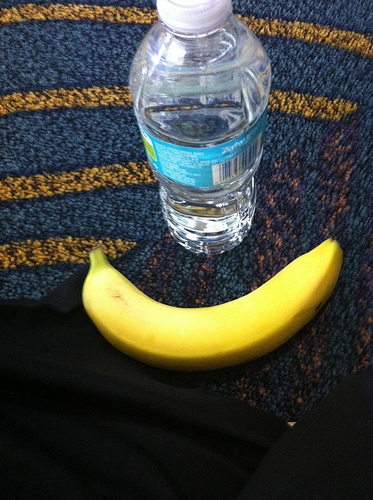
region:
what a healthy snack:
[17, 0, 361, 335]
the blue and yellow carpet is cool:
[4, 7, 120, 208]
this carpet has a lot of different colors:
[267, 158, 364, 231]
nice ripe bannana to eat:
[70, 241, 350, 373]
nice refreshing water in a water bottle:
[119, 19, 281, 262]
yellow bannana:
[80, 241, 357, 373]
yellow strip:
[1, 81, 127, 119]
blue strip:
[2, 111, 136, 170]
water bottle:
[116, 0, 292, 269]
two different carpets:
[288, 74, 372, 212]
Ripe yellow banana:
[65, 231, 357, 381]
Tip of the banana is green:
[83, 245, 117, 275]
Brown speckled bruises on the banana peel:
[102, 277, 147, 314]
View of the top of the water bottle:
[117, 1, 274, 262]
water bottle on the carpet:
[118, 1, 276, 263]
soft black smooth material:
[0, 299, 372, 499]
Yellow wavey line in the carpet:
[2, 0, 372, 276]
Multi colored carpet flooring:
[0, 0, 370, 427]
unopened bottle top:
[150, 0, 239, 47]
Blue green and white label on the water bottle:
[126, 116, 276, 196]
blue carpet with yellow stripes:
[4, 4, 371, 396]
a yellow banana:
[85, 241, 341, 368]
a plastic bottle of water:
[128, 0, 270, 255]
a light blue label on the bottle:
[136, 111, 266, 190]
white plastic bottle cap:
[156, 1, 234, 31]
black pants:
[0, 301, 371, 497]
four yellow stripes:
[0, 5, 370, 265]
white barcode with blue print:
[210, 133, 262, 185]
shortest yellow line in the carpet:
[3, 233, 139, 272]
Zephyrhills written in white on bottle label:
[220, 122, 258, 155]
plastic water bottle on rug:
[138, 0, 273, 256]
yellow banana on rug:
[68, 271, 331, 387]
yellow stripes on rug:
[20, 202, 115, 263]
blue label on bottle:
[126, 124, 275, 207]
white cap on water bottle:
[150, 3, 226, 39]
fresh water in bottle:
[169, 72, 227, 141]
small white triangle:
[286, 408, 299, 433]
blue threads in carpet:
[83, 216, 114, 245]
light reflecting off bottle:
[143, 21, 196, 79]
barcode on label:
[207, 158, 257, 185]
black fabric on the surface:
[110, 418, 199, 471]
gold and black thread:
[75, 165, 130, 189]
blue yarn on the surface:
[32, 125, 103, 149]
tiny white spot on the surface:
[278, 412, 303, 429]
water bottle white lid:
[152, 2, 245, 31]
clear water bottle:
[112, 19, 286, 248]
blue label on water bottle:
[118, 123, 289, 194]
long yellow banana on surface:
[76, 238, 346, 353]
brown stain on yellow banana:
[107, 286, 134, 305]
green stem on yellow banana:
[72, 246, 106, 261]